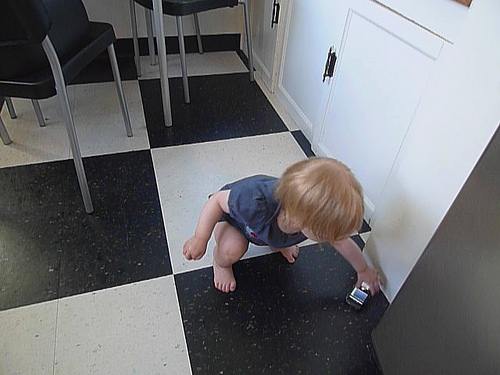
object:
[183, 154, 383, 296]
kid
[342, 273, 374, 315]
toy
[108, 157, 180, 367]
floor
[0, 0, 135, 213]
chair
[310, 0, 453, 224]
door